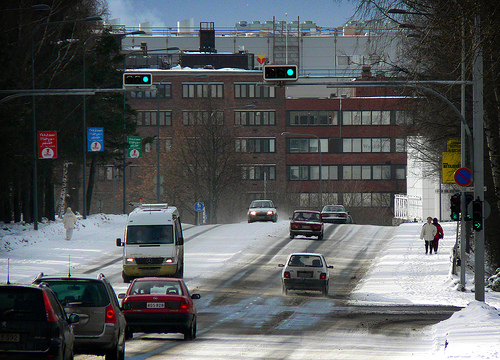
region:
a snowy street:
[43, 219, 395, 358]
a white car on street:
[278, 250, 330, 296]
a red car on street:
[118, 271, 200, 341]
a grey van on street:
[29, 269, 123, 358]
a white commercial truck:
[123, 201, 181, 278]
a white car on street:
[316, 201, 345, 220]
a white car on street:
[245, 199, 277, 224]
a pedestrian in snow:
[419, 218, 437, 254]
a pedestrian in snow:
[431, 213, 446, 254]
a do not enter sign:
[450, 164, 473, 187]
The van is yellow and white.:
[113, 196, 188, 286]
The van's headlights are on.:
[112, 195, 188, 284]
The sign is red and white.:
[36, 128, 60, 163]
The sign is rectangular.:
[36, 128, 59, 163]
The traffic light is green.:
[261, 63, 298, 83]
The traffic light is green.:
[120, 70, 154, 89]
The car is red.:
[117, 272, 204, 344]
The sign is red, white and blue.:
[84, 122, 107, 156]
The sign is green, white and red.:
[124, 132, 145, 162]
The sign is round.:
[451, 163, 475, 188]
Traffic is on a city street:
[30, 26, 460, 346]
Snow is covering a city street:
[20, 100, 462, 352]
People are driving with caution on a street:
[21, 120, 449, 351]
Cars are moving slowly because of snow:
[5, 108, 452, 353]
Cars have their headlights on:
[35, 95, 447, 335]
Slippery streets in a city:
[75, 102, 455, 342]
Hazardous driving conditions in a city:
[38, 115, 405, 355]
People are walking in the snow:
[420, 211, 446, 261]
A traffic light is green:
[260, 60, 300, 81]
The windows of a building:
[340, 135, 395, 155]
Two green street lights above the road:
[111, 50, 316, 102]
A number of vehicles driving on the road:
[0, 170, 419, 351]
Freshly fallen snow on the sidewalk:
[11, 233, 117, 268]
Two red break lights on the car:
[281, 268, 334, 286]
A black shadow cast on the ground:
[210, 288, 452, 341]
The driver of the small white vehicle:
[290, 253, 302, 266]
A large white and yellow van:
[113, 198, 193, 279]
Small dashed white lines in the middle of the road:
[212, 289, 270, 344]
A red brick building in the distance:
[105, 87, 419, 214]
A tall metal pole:
[452, 38, 498, 308]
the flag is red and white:
[31, 124, 73, 171]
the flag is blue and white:
[82, 122, 109, 159]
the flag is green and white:
[118, 131, 148, 164]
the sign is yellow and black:
[437, 144, 465, 191]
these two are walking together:
[418, 206, 447, 261]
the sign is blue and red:
[448, 164, 475, 189]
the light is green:
[136, 71, 153, 88]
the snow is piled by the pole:
[449, 292, 498, 322]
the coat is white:
[423, 223, 435, 236]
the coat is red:
[432, 221, 445, 242]